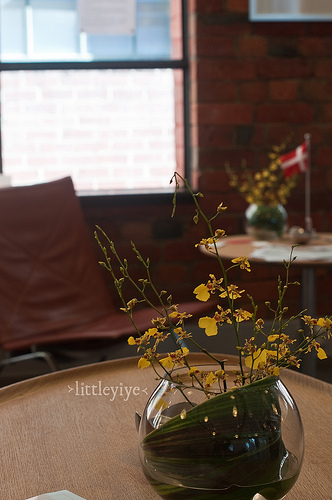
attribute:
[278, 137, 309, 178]
flag — white, red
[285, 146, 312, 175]
cross — white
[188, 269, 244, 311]
leaves — green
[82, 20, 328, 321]
wall — brick, red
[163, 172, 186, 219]
tip — broken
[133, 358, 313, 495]
vase — round, clear, glass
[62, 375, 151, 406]
stamp — watermark, white, photographer's stamp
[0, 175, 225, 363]
chair — brown, leather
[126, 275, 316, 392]
flowers — yellow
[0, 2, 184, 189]
window — half open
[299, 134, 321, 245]
flagpole — small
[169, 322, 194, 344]
flower — hanging, yellow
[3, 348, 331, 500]
table — brown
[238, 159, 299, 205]
flowers — blurry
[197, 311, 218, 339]
petals — yellow